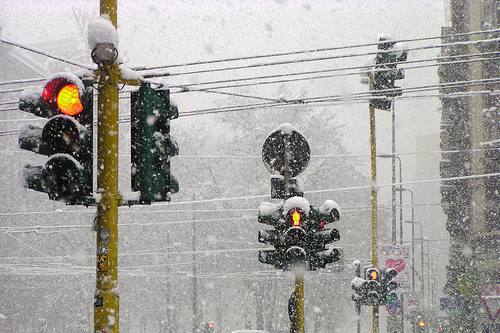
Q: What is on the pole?
A: Snow.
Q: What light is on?
A: Yellow light.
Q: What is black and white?
A: Traffic light poles.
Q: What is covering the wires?
A: Snow.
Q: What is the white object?
A: Snow.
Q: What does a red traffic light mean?
A: Stop.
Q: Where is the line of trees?
A: Behind the traffic lights.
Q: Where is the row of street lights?
A: On side of road.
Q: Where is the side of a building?
A: Left side of photo.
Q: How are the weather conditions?
A: Blizzard like.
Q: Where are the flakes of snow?
A: Blowing through the air.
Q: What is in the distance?
A: Snow covered trees.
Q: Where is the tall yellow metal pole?
A: In the street.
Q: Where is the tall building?
A: By the road.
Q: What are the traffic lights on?
A: Poles.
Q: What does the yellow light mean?
A: Caution.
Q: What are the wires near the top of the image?
A: Power lines.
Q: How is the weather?
A: Snowy.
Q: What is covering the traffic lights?
A: Snow.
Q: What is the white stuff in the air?
A: Snow.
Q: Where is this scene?
A: In a snow storm.